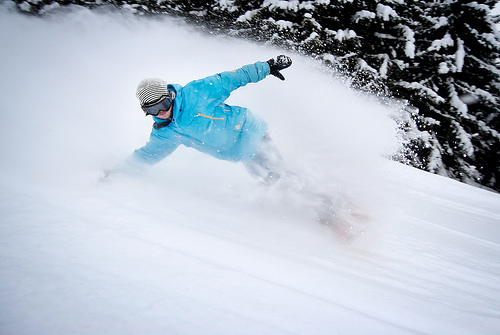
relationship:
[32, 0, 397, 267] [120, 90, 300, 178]
woman wearing jacket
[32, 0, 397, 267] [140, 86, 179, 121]
woman wearing goggles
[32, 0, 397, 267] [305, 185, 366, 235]
woman wearing ski boots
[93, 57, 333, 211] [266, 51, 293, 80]
player wearing black mitten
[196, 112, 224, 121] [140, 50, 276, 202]
zipper on jacket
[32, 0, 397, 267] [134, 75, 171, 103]
woman wearing hat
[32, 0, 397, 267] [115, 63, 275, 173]
woman wearing coat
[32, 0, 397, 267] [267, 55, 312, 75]
woman wearing glove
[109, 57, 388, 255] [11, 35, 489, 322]
person kicking up snow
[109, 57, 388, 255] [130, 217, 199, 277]
person in snow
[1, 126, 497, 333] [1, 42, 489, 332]
snow covering mountainside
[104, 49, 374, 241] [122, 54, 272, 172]
man wearing jacket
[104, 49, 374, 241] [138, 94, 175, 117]
man wearing goggles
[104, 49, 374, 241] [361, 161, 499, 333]
man falling in snow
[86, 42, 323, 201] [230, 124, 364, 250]
woman wearing ski pants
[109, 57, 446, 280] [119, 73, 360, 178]
person wearing coat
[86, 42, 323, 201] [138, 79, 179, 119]
woman wearing goggles